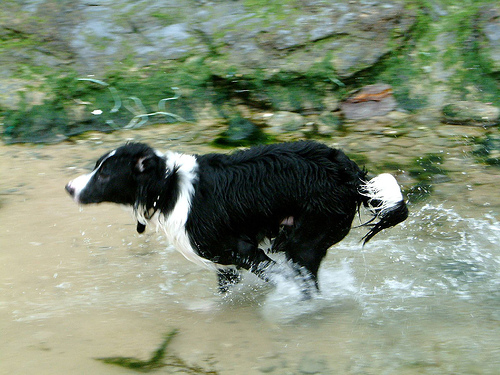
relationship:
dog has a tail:
[66, 139, 410, 316] [364, 169, 409, 247]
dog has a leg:
[66, 139, 410, 316] [285, 226, 350, 305]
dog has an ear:
[66, 139, 410, 316] [139, 152, 161, 173]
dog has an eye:
[66, 139, 410, 316] [99, 171, 111, 182]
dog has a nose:
[66, 139, 410, 316] [66, 182, 77, 200]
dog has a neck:
[66, 139, 410, 316] [139, 152, 178, 219]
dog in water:
[66, 139, 410, 316] [1, 147, 499, 373]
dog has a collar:
[66, 139, 410, 316] [135, 162, 173, 233]